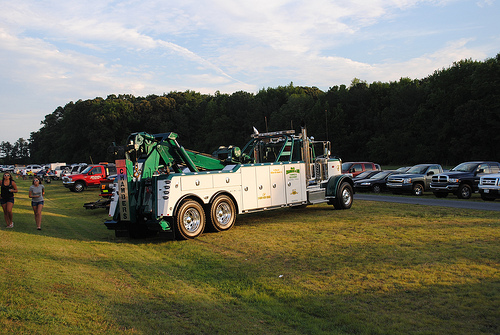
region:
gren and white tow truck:
[116, 130, 343, 224]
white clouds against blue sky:
[14, 10, 194, 85]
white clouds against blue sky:
[164, 14, 396, 71]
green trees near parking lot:
[383, 84, 495, 151]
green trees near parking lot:
[54, 119, 109, 154]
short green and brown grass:
[352, 215, 479, 317]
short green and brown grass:
[78, 247, 373, 316]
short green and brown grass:
[16, 235, 110, 317]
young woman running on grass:
[26, 177, 53, 234]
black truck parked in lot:
[433, 155, 480, 207]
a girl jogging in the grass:
[26, 175, 44, 230]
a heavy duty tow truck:
[105, 126, 355, 236]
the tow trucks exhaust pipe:
[300, 125, 310, 185]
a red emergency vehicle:
[61, 160, 111, 190]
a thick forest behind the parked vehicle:
[337, 52, 497, 157]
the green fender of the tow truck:
[325, 173, 355, 200]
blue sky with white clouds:
[0, 1, 499, 93]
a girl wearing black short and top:
[1, 172, 18, 229]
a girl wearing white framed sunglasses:
[32, 177, 40, 184]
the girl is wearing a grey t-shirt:
[28, 183, 43, 202]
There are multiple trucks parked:
[386, 145, 497, 200]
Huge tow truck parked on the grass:
[93, 116, 361, 248]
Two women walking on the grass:
[1, 163, 51, 238]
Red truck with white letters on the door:
[56, 150, 125, 197]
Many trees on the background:
[8, 30, 499, 127]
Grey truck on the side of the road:
[381, 152, 446, 198]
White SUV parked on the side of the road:
[471, 140, 498, 208]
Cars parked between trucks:
[338, 143, 413, 205]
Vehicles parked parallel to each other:
[328, 141, 498, 207]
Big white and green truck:
[86, 113, 366, 239]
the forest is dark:
[82, 92, 422, 130]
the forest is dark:
[365, 77, 497, 222]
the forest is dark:
[360, 125, 467, 240]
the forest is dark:
[372, 58, 473, 152]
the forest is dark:
[378, 87, 464, 177]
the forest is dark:
[342, 73, 453, 166]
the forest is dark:
[366, 105, 446, 195]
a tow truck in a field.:
[113, 121, 361, 252]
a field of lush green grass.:
[5, 178, 495, 333]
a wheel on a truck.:
[205, 183, 245, 246]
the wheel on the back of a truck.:
[174, 191, 209, 249]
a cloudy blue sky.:
[0, 1, 498, 136]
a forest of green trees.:
[3, 53, 497, 156]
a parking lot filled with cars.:
[341, 161, 493, 198]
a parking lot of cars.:
[0, 140, 199, 199]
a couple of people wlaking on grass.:
[0, 169, 76, 231]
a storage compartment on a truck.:
[269, 161, 291, 209]